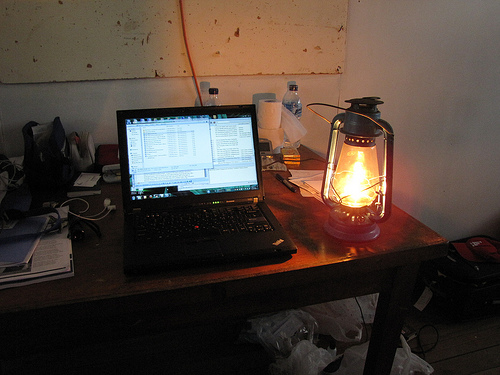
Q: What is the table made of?
A: Wood.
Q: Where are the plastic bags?
A: Under the table.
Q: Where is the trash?
A: Floor.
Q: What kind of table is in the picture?
A: Wood.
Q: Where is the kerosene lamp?
A: Next to the computer.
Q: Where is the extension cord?
A: Behind the computer.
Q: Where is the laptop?
A: On the table.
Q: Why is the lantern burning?
A: To see the laptop.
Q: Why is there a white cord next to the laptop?
A: To charge a phone.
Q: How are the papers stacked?
A: Neatly.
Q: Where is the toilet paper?
A: Behind the computer.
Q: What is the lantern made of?
A: Metal.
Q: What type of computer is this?
A: Laptop.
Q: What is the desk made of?
A: Wood.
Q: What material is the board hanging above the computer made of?
A: Wood.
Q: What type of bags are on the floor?
A: Plastic.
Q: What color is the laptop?
A: Black.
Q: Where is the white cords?
A: On the table.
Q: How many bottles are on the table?
A: 2.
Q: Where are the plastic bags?
A: On the floor.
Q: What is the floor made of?
A: Wood.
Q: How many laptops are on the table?
A: 1.